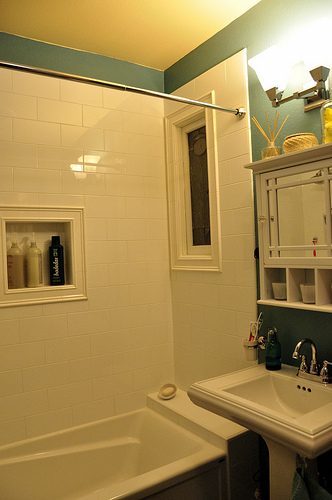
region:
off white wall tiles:
[90, 347, 135, 381]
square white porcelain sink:
[231, 373, 281, 419]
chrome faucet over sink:
[294, 337, 330, 390]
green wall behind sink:
[286, 317, 297, 331]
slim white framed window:
[161, 108, 250, 262]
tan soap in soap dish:
[154, 378, 172, 404]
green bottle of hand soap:
[263, 330, 287, 376]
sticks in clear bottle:
[256, 124, 276, 163]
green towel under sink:
[289, 484, 319, 498]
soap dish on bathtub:
[148, 380, 181, 400]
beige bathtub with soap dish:
[1, 396, 254, 497]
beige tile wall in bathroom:
[2, 89, 159, 408]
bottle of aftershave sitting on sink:
[263, 330, 284, 372]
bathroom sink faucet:
[291, 337, 330, 389]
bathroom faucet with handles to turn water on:
[288, 331, 331, 382]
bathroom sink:
[188, 339, 330, 497]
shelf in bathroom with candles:
[253, 263, 330, 321]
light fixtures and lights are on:
[250, 29, 329, 108]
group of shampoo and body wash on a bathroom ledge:
[0, 197, 93, 324]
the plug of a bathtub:
[155, 381, 180, 400]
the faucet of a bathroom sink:
[293, 336, 331, 383]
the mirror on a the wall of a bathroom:
[262, 169, 328, 258]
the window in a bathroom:
[162, 93, 225, 273]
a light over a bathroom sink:
[246, 23, 330, 104]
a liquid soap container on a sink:
[263, 324, 284, 373]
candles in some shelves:
[256, 265, 330, 307]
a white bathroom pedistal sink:
[183, 348, 328, 466]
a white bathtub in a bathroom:
[2, 389, 213, 496]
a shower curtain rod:
[2, 47, 276, 142]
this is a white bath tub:
[2, 391, 217, 499]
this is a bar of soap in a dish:
[152, 374, 185, 409]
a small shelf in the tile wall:
[0, 205, 100, 312]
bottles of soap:
[0, 212, 83, 303]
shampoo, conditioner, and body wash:
[1, 207, 94, 309]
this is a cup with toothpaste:
[241, 296, 266, 367]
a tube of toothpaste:
[244, 311, 266, 356]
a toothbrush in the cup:
[242, 302, 269, 357]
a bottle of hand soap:
[253, 317, 296, 375]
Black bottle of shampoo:
[47, 234, 68, 284]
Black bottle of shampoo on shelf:
[45, 232, 68, 287]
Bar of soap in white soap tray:
[162, 384, 174, 396]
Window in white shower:
[165, 86, 223, 270]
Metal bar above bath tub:
[0, 59, 246, 117]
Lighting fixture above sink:
[245, 23, 330, 111]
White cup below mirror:
[298, 280, 314, 301]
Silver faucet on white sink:
[290, 337, 331, 384]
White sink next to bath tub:
[185, 361, 330, 499]